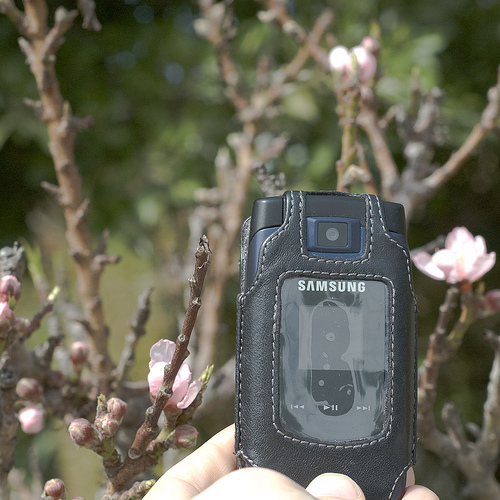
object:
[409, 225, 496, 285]
flower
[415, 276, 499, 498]
tree branch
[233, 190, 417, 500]
case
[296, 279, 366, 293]
print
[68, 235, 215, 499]
branch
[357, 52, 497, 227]
branch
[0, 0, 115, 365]
branch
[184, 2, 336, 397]
branch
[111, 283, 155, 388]
branch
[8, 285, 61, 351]
branch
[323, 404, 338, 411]
sign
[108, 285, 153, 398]
branch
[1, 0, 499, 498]
background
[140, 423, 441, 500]
person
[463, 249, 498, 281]
petal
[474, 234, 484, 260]
petal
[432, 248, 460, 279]
petal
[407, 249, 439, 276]
petal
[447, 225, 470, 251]
petal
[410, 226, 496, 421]
branch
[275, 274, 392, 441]
plastic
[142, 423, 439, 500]
hand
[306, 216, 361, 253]
camera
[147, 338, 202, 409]
flower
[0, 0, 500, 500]
tree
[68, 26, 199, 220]
foliage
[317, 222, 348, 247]
lense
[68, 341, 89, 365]
flower buds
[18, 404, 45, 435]
flower buds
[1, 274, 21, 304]
flower buds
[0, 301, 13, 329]
flower buds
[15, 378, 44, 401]
flower buds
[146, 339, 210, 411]
petal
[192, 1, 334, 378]
branch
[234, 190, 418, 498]
thread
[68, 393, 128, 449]
buds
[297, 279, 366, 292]
samsung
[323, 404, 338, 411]
button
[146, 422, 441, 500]
fingers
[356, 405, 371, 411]
sign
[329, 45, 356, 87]
petal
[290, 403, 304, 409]
sign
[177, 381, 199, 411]
petal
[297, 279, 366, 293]
name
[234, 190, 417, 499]
cell phone